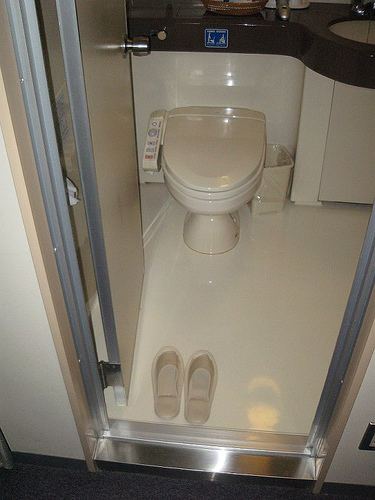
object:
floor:
[91, 199, 372, 434]